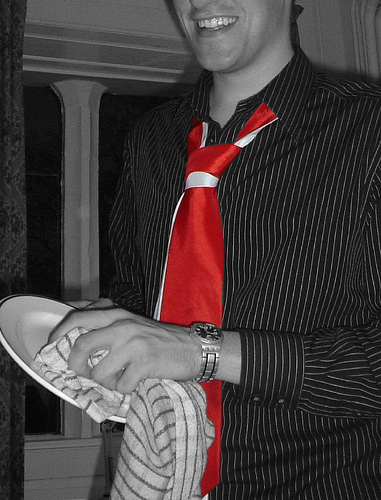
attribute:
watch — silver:
[188, 323, 225, 384]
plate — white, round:
[0, 292, 76, 406]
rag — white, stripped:
[32, 341, 216, 499]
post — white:
[49, 79, 111, 299]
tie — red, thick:
[153, 143, 241, 325]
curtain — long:
[1, 1, 24, 500]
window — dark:
[23, 26, 207, 301]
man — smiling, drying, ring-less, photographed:
[49, 1, 381, 500]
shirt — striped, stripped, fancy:
[109, 48, 380, 499]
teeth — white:
[199, 18, 239, 28]